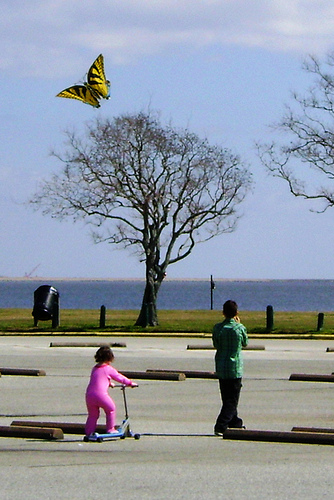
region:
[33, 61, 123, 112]
A yellow and black butterfly flying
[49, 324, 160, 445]
A girl riding a scooter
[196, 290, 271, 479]
A man taking a picture of the water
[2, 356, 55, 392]
Parking lot bumps in front of spaces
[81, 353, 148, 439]
The little girl is wearing pink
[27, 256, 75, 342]
A metal trash can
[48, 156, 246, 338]
The tree has lost its leaves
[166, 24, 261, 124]
The sky is blue with some clouds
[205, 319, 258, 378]
The man is wearing a green shirt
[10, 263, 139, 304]
The water is still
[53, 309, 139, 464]
little girl dressed in pink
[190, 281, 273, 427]
man wearing green shirt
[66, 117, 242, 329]
tree with no leaves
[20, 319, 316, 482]
many logs in parking lot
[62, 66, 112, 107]
black and yellow butterfly flying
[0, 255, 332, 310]
water visible in background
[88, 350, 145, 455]
girl on scooter in photo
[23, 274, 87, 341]
black garbage can in photo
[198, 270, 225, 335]
metal pole in grass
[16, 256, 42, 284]
something on land in distance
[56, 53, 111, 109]
a black and yellow butterfly kite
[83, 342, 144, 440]
little girl on a scooter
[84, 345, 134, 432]
a little girl in a pink jumper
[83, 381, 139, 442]
a blue toy scooter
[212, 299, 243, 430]
a boy flying a kite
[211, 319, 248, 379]
a boy's green shirt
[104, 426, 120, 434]
a girl's right foot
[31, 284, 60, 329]
a composting trash bin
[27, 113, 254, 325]
a tree with no leaves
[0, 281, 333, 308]
a large body of water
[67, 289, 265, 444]
two kids in a park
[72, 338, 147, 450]
little girl wears a pink suit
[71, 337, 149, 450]
kid has a blue scooter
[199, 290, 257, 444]
boy wears a green shirt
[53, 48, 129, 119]
a kite in shape of papillon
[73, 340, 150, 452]
kid has right feet on scooter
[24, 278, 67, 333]
a black trash can on grass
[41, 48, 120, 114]
kite butterfly is yellow and black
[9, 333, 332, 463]
court has several wood sticks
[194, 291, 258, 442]
boy has black hair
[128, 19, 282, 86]
white clouds in blue sky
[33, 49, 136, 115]
black and yellow butterfly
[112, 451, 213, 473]
the grey pavement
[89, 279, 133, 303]
deep blue lake water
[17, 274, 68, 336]
a black litter container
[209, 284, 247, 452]
a boy in a green shirt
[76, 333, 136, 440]
a girl in a pink outfit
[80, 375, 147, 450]
a razor scooter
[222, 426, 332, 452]
a parking barrier